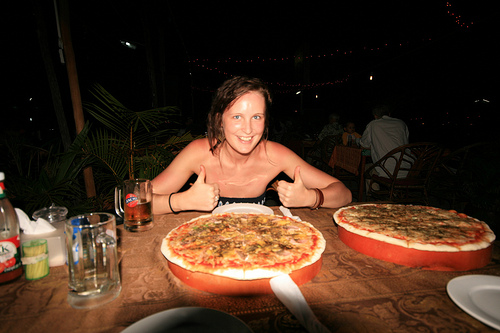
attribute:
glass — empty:
[127, 188, 155, 225]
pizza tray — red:
[338, 232, 497, 269]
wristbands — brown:
[312, 187, 324, 208]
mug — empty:
[61, 213, 126, 305]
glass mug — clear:
[112, 176, 153, 233]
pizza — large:
[332, 197, 494, 257]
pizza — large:
[158, 205, 323, 275]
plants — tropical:
[58, 80, 171, 207]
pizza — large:
[155, 210, 326, 297]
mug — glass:
[121, 176, 168, 236]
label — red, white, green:
[0, 230, 24, 272]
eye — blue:
[248, 111, 261, 122]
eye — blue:
[228, 111, 243, 122]